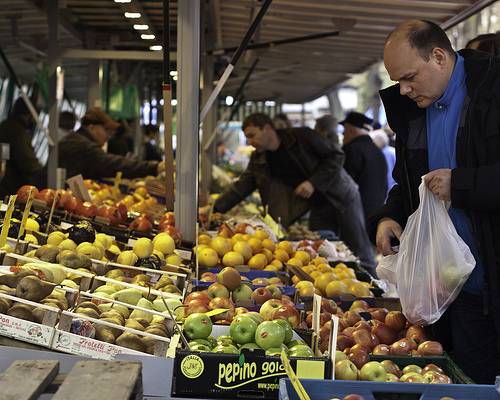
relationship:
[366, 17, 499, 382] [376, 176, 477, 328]
man with bag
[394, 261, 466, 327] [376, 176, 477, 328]
fruit filled in a bag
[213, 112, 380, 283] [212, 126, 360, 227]
man in a jacket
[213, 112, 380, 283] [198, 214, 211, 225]
man reaching for fruit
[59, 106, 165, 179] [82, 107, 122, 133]
man wearing brown cap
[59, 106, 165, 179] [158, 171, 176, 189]
man reaching for fruit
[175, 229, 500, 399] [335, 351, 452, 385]
box of apples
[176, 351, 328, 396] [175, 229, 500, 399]
writing on side of box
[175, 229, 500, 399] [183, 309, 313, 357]
box of apples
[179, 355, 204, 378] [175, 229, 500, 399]
circle on side of box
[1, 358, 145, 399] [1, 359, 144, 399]
pallet in pallet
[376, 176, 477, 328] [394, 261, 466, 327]
bag of fruit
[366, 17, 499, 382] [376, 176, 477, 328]
man holding bag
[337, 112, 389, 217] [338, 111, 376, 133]
elderly man in a black hat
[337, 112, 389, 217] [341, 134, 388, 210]
elderly man in a black jacket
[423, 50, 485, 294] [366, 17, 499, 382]
shirt worn by man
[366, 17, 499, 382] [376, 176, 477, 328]
man putting fruit in a bag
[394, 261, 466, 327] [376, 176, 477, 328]
fruit inside a bag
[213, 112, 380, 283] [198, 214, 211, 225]
man reaching over to get fruit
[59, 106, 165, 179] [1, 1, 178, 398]
person on left of market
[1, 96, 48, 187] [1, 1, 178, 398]
person on left of market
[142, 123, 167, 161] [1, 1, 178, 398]
person on left of market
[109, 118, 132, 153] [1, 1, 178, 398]
person on left of market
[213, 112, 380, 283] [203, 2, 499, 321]
person on right of market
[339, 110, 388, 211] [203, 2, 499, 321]
person on right of market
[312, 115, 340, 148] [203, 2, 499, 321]
person on right of market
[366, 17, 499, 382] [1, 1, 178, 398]
person on right of market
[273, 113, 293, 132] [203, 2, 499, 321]
person on right of market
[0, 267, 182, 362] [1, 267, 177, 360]
pears on shelf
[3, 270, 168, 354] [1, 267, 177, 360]
pears on shelf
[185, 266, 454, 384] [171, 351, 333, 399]
apples on writing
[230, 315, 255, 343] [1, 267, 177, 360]
green apple on shelf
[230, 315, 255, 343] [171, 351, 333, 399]
green apple on writing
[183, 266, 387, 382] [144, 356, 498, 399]
red and yellow apple on top of shelf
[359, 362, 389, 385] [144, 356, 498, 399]
red and yellow apple on top of shelf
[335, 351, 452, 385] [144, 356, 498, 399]
apples on top of shelf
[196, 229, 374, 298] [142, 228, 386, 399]
oranges on top of shelf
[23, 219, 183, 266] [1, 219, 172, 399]
lemon on top of shelf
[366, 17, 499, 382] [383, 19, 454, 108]
man with head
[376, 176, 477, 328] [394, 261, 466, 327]
plastic bag with fruit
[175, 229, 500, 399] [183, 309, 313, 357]
box of green pepino apples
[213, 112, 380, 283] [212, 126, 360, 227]
man with brown jacket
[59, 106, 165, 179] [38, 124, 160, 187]
man with jacket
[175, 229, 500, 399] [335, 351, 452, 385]
box of fruits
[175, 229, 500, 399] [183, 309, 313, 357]
box of fruits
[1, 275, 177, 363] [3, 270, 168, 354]
box of fruits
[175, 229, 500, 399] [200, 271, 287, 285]
box of fruits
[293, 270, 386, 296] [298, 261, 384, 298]
box of fruits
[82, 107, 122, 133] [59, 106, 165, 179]
hat on man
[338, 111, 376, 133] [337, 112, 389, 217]
hat on man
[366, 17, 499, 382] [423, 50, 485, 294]
man with shirt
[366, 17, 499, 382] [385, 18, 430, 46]
man going bald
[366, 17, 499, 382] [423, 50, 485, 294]
man wearing shirt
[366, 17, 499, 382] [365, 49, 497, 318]
man wearing coat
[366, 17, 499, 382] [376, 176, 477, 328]
man holding white bag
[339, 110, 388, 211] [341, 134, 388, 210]
person wearing a dark coat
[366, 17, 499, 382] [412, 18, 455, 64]
man has dark hair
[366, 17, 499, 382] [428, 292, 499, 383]
man wearing pants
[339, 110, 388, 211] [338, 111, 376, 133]
person wearing a hat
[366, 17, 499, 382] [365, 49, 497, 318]
man wearing a coat